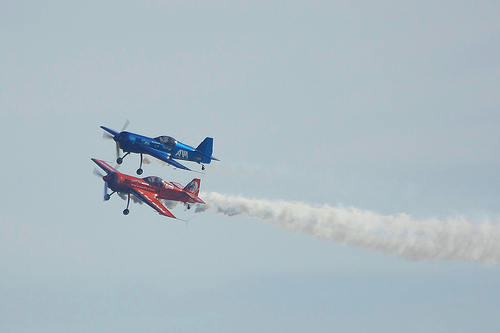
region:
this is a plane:
[84, 159, 202, 227]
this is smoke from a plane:
[215, 191, 279, 228]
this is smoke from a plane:
[312, 189, 357, 257]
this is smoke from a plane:
[392, 212, 486, 297]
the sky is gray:
[178, 49, 283, 130]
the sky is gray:
[267, 43, 414, 145]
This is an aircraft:
[91, 110, 233, 174]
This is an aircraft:
[86, 155, 221, 222]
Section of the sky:
[358, 270, 493, 331]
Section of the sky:
[187, 263, 358, 332]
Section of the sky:
[16, 248, 167, 331]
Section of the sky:
[279, 169, 489, 264]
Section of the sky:
[308, 118, 498, 203]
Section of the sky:
[2, 98, 84, 260]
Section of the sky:
[159, 17, 351, 123]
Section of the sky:
[5, 5, 147, 113]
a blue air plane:
[74, 112, 236, 168]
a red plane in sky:
[73, 163, 216, 224]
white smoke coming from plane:
[208, 189, 371, 232]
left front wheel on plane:
[114, 208, 139, 218]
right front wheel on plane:
[96, 193, 113, 202]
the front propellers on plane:
[84, 163, 106, 190]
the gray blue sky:
[139, 58, 484, 122]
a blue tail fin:
[193, 135, 231, 155]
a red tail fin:
[183, 175, 208, 190]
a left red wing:
[132, 199, 188, 236]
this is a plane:
[94, 115, 244, 183]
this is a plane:
[75, 133, 217, 248]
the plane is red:
[80, 149, 211, 236]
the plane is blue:
[80, 109, 232, 194]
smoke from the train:
[279, 200, 336, 267]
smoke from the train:
[345, 202, 393, 288]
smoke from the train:
[408, 194, 483, 286]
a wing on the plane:
[130, 185, 181, 239]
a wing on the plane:
[145, 140, 191, 180]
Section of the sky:
[251, 200, 381, 306]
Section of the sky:
[269, 264, 439, 319]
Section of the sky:
[3, 201, 115, 284]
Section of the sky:
[308, 62, 460, 184]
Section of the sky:
[68, 25, 240, 100]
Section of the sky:
[5, 14, 81, 160]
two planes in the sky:
[85, 117, 221, 229]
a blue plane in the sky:
[97, 120, 222, 177]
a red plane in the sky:
[90, 155, 210, 223]